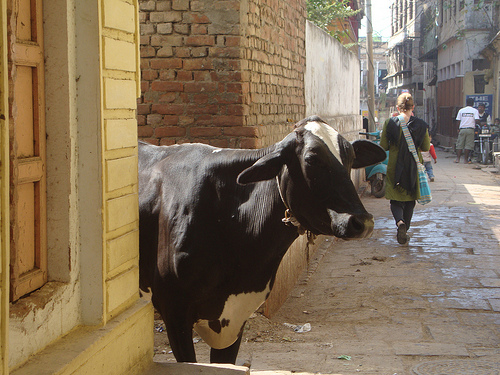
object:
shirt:
[454, 106, 479, 130]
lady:
[378, 91, 433, 248]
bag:
[395, 114, 433, 207]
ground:
[153, 143, 500, 373]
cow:
[137, 115, 390, 366]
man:
[451, 97, 481, 165]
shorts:
[455, 128, 476, 151]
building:
[430, 0, 500, 151]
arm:
[428, 143, 437, 160]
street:
[156, 141, 498, 370]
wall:
[138, 0, 306, 151]